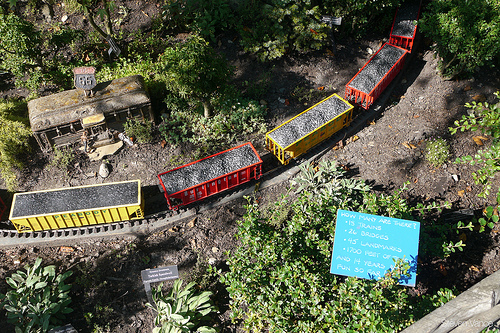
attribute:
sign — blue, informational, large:
[328, 204, 423, 291]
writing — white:
[337, 209, 418, 278]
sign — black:
[138, 263, 182, 286]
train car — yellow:
[7, 176, 150, 236]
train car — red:
[153, 136, 266, 215]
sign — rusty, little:
[67, 64, 102, 98]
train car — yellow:
[262, 88, 359, 168]